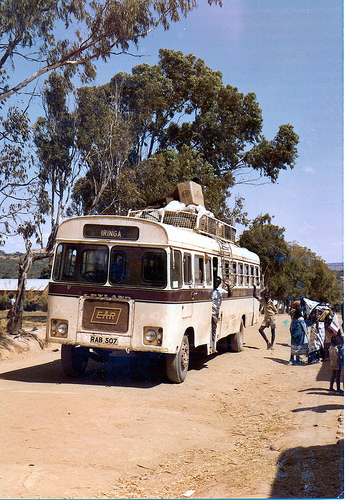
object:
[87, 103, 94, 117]
leaves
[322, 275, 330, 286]
leaves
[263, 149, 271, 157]
leaves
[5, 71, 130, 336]
tree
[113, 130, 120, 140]
leaves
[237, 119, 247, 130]
leaves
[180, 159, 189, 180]
leaves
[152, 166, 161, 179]
green leaves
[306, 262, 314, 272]
leaves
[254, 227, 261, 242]
leaves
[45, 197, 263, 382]
bus